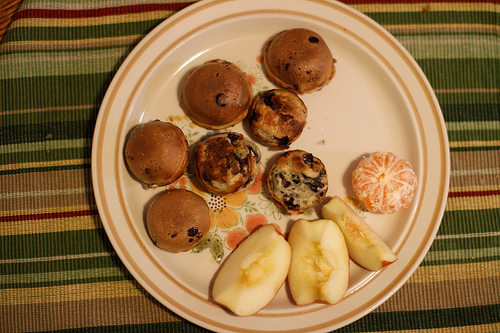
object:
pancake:
[263, 28, 338, 96]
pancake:
[180, 59, 252, 130]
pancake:
[248, 88, 308, 150]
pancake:
[193, 132, 262, 195]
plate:
[90, 0, 450, 332]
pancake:
[266, 149, 329, 215]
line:
[97, 0, 447, 332]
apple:
[211, 224, 292, 316]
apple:
[287, 218, 350, 305]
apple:
[321, 195, 398, 272]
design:
[165, 54, 348, 221]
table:
[0, 0, 100, 77]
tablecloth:
[411, 268, 500, 333]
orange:
[351, 151, 418, 214]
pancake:
[147, 189, 211, 254]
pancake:
[125, 119, 189, 189]